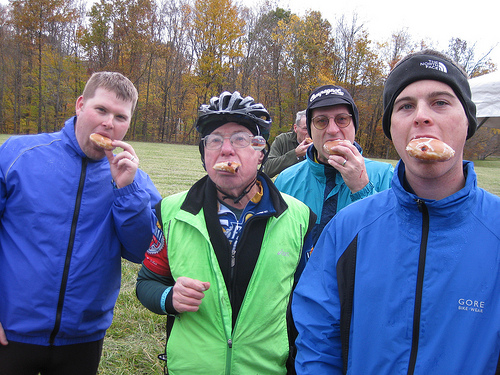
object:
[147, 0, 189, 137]
tree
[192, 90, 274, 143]
helmet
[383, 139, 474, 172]
danish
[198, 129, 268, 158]
glasses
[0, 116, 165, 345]
windbreaker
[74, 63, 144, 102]
haircut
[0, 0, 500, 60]
sky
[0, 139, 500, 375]
field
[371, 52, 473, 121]
beanie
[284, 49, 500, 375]
man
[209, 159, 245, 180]
doughnut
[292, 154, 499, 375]
jacket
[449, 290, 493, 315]
logo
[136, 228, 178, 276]
patch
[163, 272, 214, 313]
hand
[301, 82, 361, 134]
hat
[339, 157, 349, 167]
ring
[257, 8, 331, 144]
trees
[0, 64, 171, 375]
men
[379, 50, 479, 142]
hat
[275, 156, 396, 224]
windbreaker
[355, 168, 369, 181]
scratch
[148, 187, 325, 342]
vest